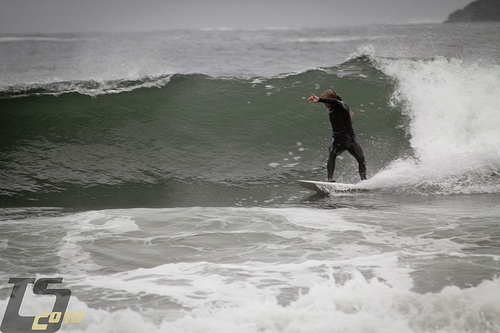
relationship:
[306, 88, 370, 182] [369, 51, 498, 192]
man surfing wave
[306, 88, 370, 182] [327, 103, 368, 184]
man in wet suit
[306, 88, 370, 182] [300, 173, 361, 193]
man on surf board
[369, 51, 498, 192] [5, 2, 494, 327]
wave in ocean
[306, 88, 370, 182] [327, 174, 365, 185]
surfer hanging ten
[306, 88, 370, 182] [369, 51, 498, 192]
surfer shredding waves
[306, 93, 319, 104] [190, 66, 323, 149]
left hand on air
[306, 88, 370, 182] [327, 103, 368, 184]
man in black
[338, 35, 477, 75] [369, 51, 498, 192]
water spray from wave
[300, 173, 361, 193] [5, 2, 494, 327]
surf board in water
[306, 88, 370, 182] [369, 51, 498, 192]
man enjoying wave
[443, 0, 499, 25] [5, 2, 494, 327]
land behind water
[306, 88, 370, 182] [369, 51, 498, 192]
surfer on wave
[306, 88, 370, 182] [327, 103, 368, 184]
man wearing wet suit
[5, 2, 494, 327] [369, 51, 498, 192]
water on wave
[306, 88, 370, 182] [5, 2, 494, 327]
surfer in ocean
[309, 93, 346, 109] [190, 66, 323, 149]
arm in air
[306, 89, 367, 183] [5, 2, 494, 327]
man on beach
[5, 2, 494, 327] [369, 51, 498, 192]
ocean from wave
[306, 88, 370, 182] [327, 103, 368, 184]
surfer wearing wet suit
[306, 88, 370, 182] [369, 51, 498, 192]
man riding wave